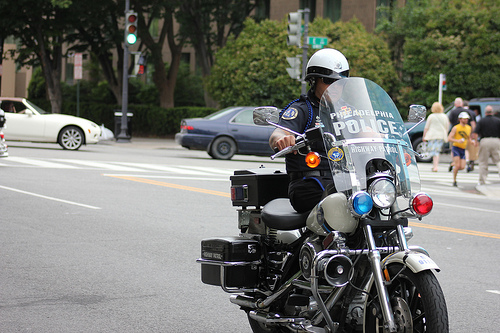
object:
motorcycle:
[195, 75, 451, 333]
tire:
[56, 124, 85, 151]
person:
[421, 100, 452, 172]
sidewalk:
[94, 136, 287, 164]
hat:
[456, 111, 472, 119]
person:
[447, 112, 469, 188]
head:
[456, 111, 470, 125]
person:
[472, 105, 500, 187]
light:
[410, 192, 434, 217]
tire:
[209, 135, 237, 159]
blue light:
[351, 192, 375, 216]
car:
[0, 96, 103, 151]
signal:
[288, 10, 299, 23]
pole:
[299, 6, 310, 95]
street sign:
[306, 34, 331, 48]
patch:
[279, 106, 299, 121]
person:
[445, 111, 476, 187]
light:
[303, 149, 321, 169]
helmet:
[303, 47, 352, 81]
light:
[125, 31, 138, 44]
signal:
[125, 11, 138, 24]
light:
[367, 177, 398, 211]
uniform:
[278, 100, 338, 216]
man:
[268, 47, 354, 307]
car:
[174, 105, 284, 161]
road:
[4, 147, 500, 332]